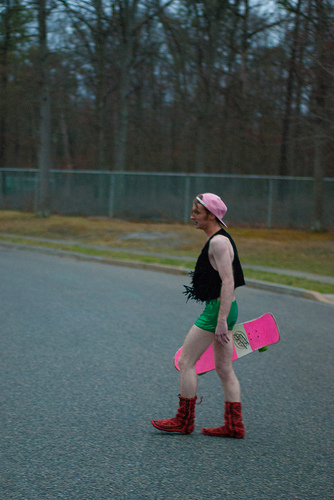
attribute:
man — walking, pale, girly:
[165, 188, 260, 449]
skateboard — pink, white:
[167, 336, 279, 369]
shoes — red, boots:
[173, 386, 257, 453]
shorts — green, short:
[187, 286, 235, 328]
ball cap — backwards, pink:
[191, 182, 229, 228]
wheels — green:
[262, 341, 272, 354]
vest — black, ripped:
[189, 229, 270, 294]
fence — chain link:
[267, 184, 305, 211]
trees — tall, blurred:
[175, 55, 244, 102]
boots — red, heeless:
[153, 390, 239, 450]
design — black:
[228, 335, 247, 347]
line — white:
[229, 323, 255, 349]